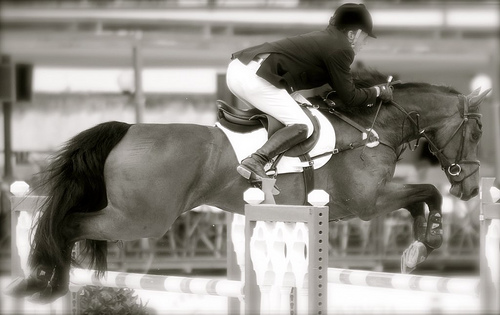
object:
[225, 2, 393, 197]
jockey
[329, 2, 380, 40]
hat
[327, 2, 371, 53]
head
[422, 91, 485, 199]
bridle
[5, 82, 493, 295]
horse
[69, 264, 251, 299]
bar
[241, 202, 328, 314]
box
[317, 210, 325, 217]
holes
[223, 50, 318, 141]
pants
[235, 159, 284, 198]
shoe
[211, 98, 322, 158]
saddle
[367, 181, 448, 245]
leg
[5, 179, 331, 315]
hurdle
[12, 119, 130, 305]
tail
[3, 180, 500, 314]
obstacle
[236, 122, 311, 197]
boot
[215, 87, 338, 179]
pad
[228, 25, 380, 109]
coat